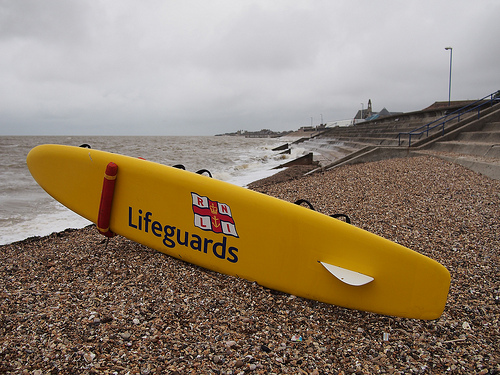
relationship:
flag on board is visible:
[190, 195, 239, 236] [24, 141, 453, 325]